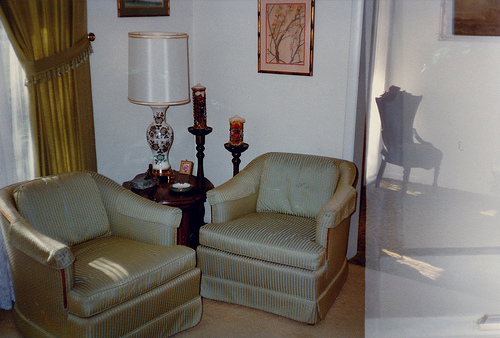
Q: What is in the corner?
A: A lamp.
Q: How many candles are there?
A: Two.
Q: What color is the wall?
A: White.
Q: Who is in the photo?
A: Nobody.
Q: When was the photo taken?
A: Daytime.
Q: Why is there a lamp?
A: To light up the room.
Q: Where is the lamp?
A: In the corner.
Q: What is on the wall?
A: Pictures.